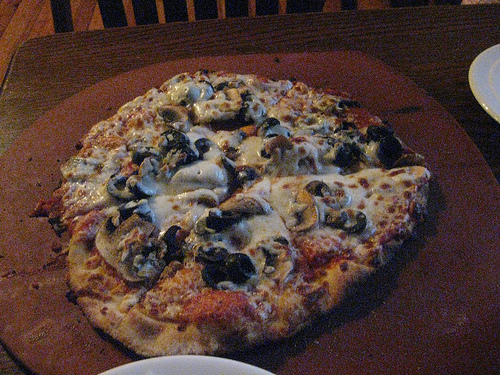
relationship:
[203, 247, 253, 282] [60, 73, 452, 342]
olives on a pizza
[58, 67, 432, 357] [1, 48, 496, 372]
pizza on plate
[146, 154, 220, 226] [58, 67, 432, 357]
cheese on pizza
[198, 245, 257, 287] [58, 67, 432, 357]
olives in a pizza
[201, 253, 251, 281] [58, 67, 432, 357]
olive on pizza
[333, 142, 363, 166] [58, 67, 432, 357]
olive on pizza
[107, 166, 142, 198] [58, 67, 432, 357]
olive on pizza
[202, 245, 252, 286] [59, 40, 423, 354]
olive on pizza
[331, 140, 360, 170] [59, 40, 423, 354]
olive on pizza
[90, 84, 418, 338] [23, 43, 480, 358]
pizza on board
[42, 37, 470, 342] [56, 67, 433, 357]
pizza on table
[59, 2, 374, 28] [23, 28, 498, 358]
chair against table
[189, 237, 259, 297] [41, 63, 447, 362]
olives on pizza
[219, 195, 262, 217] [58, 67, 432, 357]
murshrooms on pizza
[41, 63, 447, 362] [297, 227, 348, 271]
pizza on sauce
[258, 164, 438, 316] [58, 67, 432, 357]
slice of pizza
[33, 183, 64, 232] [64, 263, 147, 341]
sauce on crust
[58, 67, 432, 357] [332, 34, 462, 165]
pizza on a stone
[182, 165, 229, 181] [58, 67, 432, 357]
cheese on a pizza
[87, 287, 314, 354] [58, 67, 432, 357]
crust of a pizza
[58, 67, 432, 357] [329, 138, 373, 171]
pizza with olive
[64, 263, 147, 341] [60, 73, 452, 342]
crust of a pizza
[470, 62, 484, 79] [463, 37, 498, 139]
part of a plate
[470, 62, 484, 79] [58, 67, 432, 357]
part of a pizza